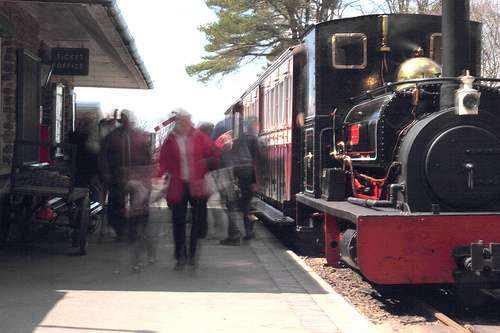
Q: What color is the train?
A: Black.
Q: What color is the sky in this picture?
A: White.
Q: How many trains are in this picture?
A: One.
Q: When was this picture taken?
A: Daytime.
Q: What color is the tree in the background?
A: Green.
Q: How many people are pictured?
A: Four.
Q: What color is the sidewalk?
A: Grey.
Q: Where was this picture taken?
A: A train station.